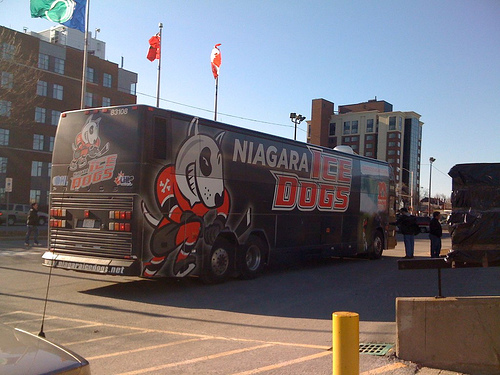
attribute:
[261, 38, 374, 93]
clouds — white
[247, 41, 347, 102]
sky — blue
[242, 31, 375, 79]
clouds — white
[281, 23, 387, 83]
clouds — white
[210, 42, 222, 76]
red design — white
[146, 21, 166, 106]
flag — flying, red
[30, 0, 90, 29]
flag — blue, green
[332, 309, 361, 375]
post — yellow, metal, thick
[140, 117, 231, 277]
mascot — cartoon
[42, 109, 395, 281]
bus — black, parked, tour bus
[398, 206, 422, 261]
man — standing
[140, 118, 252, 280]
mascot — playing hockey, dog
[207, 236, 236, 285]
wheels — black, round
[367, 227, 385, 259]
wheels — round, black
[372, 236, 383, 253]
hub caps — silver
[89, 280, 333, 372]
street — black asphalt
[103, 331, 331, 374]
stripes — yellow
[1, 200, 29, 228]
suv — parked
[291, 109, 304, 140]
lights — street lights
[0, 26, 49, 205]
building — large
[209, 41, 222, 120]
flag — red, white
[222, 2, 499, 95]
sky — blue